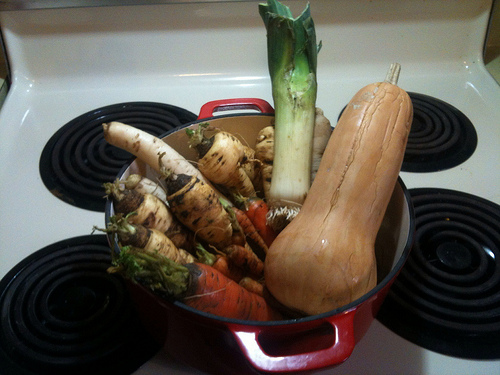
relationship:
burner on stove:
[398, 187, 499, 357] [5, 7, 497, 369]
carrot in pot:
[116, 250, 284, 325] [87, 82, 431, 371]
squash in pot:
[304, 74, 409, 301] [360, 231, 419, 356]